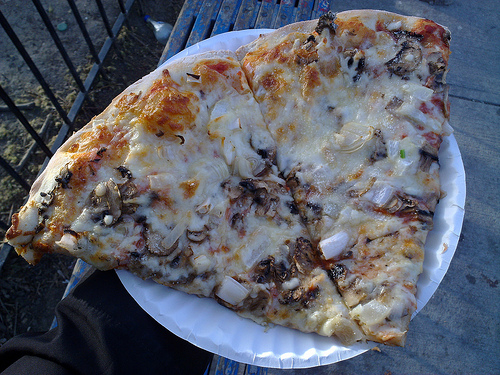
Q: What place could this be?
A: It is a sidewalk.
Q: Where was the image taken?
A: It was taken at the sidewalk.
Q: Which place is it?
A: It is a sidewalk.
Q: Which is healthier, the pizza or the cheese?
A: The cheese is healthier than the pizza.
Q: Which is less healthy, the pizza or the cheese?
A: The pizza is less healthy than the cheese.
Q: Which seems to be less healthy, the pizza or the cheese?
A: The pizza is less healthy than the cheese.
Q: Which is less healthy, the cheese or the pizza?
A: The pizza is less healthy than the cheese.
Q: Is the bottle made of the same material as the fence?
A: No, the bottle is made of plastic and the fence is made of metal.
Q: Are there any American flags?
A: No, there are no American flags.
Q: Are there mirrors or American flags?
A: No, there are no American flags or mirrors.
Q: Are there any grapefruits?
A: No, there are no grapefruits.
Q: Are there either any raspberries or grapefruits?
A: No, there are no grapefruits or raspberries.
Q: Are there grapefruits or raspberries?
A: No, there are no grapefruits or raspberries.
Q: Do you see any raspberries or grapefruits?
A: No, there are no grapefruits or raspberries.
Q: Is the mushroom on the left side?
A: Yes, the mushroom is on the left of the image.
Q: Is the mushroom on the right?
A: No, the mushroom is on the left of the image.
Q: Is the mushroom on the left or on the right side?
A: The mushroom is on the left of the image.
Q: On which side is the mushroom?
A: The mushroom is on the left of the image.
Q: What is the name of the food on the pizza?
A: The food is a mushroom.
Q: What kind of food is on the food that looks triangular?
A: The food is a mushroom.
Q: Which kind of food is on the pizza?
A: The food is a mushroom.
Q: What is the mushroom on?
A: The mushroom is on the pizza.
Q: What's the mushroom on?
A: The mushroom is on the pizza.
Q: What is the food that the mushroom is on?
A: The food is a pizza.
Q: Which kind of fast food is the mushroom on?
A: The mushroom is on the pizza.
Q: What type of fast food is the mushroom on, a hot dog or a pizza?
A: The mushroom is on a pizza.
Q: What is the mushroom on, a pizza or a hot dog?
A: The mushroom is on a pizza.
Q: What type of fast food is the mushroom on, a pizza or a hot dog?
A: The mushroom is on a pizza.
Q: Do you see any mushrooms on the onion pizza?
A: Yes, there is a mushroom on the pizza.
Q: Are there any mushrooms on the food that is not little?
A: Yes, there is a mushroom on the pizza.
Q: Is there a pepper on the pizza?
A: No, there is a mushroom on the pizza.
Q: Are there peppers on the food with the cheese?
A: No, there is a mushroom on the pizza.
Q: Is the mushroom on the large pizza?
A: Yes, the mushroom is on the pizza.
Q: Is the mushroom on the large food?
A: Yes, the mushroom is on the pizza.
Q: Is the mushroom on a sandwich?
A: No, the mushroom is on the pizza.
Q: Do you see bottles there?
A: Yes, there is a bottle.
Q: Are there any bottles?
A: Yes, there is a bottle.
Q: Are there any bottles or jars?
A: Yes, there is a bottle.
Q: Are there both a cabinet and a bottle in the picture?
A: No, there is a bottle but no cabinets.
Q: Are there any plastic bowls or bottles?
A: Yes, there is a plastic bottle.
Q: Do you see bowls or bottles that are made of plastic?
A: Yes, the bottle is made of plastic.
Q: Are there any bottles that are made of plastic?
A: Yes, there is a bottle that is made of plastic.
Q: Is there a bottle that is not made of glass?
A: Yes, there is a bottle that is made of plastic.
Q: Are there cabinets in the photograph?
A: No, there are no cabinets.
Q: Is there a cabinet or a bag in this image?
A: No, there are no cabinets or bags.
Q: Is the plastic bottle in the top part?
A: Yes, the bottle is in the top of the image.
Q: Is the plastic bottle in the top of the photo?
A: Yes, the bottle is in the top of the image.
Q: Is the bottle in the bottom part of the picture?
A: No, the bottle is in the top of the image.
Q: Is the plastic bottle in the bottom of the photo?
A: No, the bottle is in the top of the image.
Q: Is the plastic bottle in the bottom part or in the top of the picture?
A: The bottle is in the top of the image.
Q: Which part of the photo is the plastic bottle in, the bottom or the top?
A: The bottle is in the top of the image.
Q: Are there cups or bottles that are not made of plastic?
A: No, there is a bottle but it is made of plastic.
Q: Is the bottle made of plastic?
A: Yes, the bottle is made of plastic.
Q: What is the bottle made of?
A: The bottle is made of plastic.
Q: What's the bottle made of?
A: The bottle is made of plastic.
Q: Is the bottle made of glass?
A: No, the bottle is made of plastic.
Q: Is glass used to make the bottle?
A: No, the bottle is made of plastic.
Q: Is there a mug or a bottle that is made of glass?
A: No, there is a bottle but it is made of plastic.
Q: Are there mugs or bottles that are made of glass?
A: No, there is a bottle but it is made of plastic.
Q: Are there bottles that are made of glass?
A: No, there is a bottle but it is made of plastic.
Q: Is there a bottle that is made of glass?
A: No, there is a bottle but it is made of plastic.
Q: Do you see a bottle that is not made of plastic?
A: No, there is a bottle but it is made of plastic.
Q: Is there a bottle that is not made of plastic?
A: No, there is a bottle but it is made of plastic.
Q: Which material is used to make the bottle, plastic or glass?
A: The bottle is made of plastic.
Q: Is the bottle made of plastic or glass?
A: The bottle is made of plastic.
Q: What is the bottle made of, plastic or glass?
A: The bottle is made of plastic.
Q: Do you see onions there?
A: Yes, there is an onion.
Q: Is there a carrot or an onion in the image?
A: Yes, there is an onion.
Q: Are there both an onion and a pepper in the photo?
A: No, there is an onion but no peppers.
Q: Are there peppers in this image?
A: No, there are no peppers.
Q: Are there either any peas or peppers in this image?
A: No, there are no peppers or peas.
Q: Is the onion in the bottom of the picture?
A: Yes, the onion is in the bottom of the image.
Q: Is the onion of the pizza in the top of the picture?
A: No, the onion is in the bottom of the image.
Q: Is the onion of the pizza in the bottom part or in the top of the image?
A: The onion is in the bottom of the image.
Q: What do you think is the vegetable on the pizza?
A: The vegetable is an onion.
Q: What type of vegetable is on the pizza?
A: The vegetable is an onion.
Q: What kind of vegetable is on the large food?
A: The vegetable is an onion.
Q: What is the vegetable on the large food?
A: The vegetable is an onion.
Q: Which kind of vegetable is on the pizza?
A: The vegetable is an onion.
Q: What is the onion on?
A: The onion is on the pizza.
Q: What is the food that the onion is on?
A: The food is a pizza.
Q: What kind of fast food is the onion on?
A: The onion is on the pizza.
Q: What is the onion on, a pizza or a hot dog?
A: The onion is on a pizza.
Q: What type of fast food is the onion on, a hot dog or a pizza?
A: The onion is on a pizza.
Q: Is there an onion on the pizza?
A: Yes, there is an onion on the pizza.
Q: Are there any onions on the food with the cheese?
A: Yes, there is an onion on the pizza.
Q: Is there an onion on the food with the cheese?
A: Yes, there is an onion on the pizza.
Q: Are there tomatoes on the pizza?
A: No, there is an onion on the pizza.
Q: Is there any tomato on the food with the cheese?
A: No, there is an onion on the pizza.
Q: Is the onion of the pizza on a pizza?
A: Yes, the onion is on a pizza.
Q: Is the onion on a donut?
A: No, the onion is on a pizza.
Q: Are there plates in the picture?
A: Yes, there is a plate.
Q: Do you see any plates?
A: Yes, there is a plate.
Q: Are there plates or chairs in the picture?
A: Yes, there is a plate.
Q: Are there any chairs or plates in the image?
A: Yes, there is a plate.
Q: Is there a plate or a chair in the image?
A: Yes, there is a plate.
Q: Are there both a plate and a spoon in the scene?
A: No, there is a plate but no spoons.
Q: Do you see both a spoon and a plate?
A: No, there is a plate but no spoons.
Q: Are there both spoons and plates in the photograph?
A: No, there is a plate but no spoons.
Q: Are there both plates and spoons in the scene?
A: No, there is a plate but no spoons.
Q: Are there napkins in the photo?
A: No, there are no napkins.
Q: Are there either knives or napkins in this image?
A: No, there are no napkins or knives.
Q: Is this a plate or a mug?
A: This is a plate.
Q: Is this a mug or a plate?
A: This is a plate.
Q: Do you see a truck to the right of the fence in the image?
A: No, there is a plate to the right of the fence.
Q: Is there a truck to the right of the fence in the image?
A: No, there is a plate to the right of the fence.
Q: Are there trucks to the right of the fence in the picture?
A: No, there is a plate to the right of the fence.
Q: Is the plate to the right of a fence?
A: Yes, the plate is to the right of a fence.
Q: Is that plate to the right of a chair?
A: No, the plate is to the right of a fence.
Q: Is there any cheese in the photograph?
A: Yes, there is cheese.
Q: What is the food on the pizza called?
A: The food is cheese.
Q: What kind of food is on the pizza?
A: The food is cheese.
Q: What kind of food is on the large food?
A: The food is cheese.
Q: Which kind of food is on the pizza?
A: The food is cheese.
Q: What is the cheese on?
A: The cheese is on the pizza.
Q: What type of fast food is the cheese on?
A: The cheese is on the pizza.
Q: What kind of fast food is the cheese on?
A: The cheese is on the pizza.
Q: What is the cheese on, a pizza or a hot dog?
A: The cheese is on a pizza.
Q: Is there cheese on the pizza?
A: Yes, there is cheese on the pizza.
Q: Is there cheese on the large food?
A: Yes, there is cheese on the pizza.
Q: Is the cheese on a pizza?
A: Yes, the cheese is on a pizza.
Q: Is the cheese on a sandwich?
A: No, the cheese is on a pizza.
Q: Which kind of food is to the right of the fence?
A: The food is cheese.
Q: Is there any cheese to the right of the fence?
A: Yes, there is cheese to the right of the fence.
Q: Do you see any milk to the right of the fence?
A: No, there is cheese to the right of the fence.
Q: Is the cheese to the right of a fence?
A: Yes, the cheese is to the right of a fence.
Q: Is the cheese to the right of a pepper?
A: No, the cheese is to the right of a fence.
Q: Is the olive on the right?
A: Yes, the olive is on the right of the image.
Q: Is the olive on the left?
A: No, the olive is on the right of the image.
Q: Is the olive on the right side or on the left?
A: The olive is on the right of the image.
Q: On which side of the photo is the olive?
A: The olive is on the right of the image.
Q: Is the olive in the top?
A: Yes, the olive is in the top of the image.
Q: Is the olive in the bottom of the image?
A: No, the olive is in the top of the image.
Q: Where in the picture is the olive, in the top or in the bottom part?
A: The olive is in the top of the image.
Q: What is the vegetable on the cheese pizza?
A: The vegetable is an olive.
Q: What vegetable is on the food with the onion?
A: The vegetable is an olive.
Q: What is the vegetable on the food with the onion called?
A: The vegetable is an olive.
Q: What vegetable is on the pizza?
A: The vegetable is an olive.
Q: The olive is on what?
A: The olive is on the pizza.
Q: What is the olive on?
A: The olive is on the pizza.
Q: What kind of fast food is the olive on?
A: The olive is on the pizza.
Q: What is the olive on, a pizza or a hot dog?
A: The olive is on a pizza.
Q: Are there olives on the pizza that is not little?
A: Yes, there is an olive on the pizza.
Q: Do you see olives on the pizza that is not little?
A: Yes, there is an olive on the pizza.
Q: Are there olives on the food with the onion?
A: Yes, there is an olive on the pizza.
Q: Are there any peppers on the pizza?
A: No, there is an olive on the pizza.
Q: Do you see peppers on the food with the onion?
A: No, there is an olive on the pizza.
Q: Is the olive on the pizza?
A: Yes, the olive is on the pizza.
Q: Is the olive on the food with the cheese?
A: Yes, the olive is on the pizza.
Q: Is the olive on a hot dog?
A: No, the olive is on the pizza.